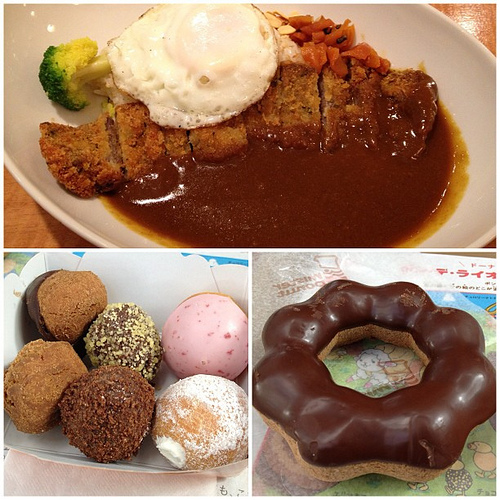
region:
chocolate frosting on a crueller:
[276, 376, 318, 412]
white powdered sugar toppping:
[207, 386, 227, 416]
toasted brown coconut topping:
[85, 395, 135, 420]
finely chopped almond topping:
[121, 325, 141, 345]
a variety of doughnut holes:
[0, 260, 239, 469]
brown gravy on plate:
[259, 177, 326, 222]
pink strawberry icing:
[187, 319, 228, 354]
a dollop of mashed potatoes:
[149, 40, 232, 97]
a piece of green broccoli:
[40, 48, 97, 102]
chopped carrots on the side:
[314, 19, 363, 66]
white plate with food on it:
[0, 29, 493, 242]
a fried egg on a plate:
[108, 8, 284, 106]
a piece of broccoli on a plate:
[30, 31, 152, 116]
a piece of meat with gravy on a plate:
[46, 62, 470, 229]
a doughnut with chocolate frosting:
[296, 264, 494, 447]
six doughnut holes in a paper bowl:
[3, 266, 237, 470]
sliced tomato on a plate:
[256, 27, 395, 79]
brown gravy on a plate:
[99, 96, 455, 256]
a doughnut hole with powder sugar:
[139, 369, 241, 499]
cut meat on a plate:
[47, 74, 437, 197]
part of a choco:
[333, 400, 361, 434]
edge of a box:
[144, 453, 184, 482]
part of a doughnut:
[302, 375, 350, 461]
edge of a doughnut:
[295, 427, 360, 479]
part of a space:
[368, 344, 403, 386]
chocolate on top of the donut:
[291, 287, 485, 478]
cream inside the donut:
[153, 391, 202, 482]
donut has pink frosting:
[173, 289, 251, 369]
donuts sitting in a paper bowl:
[25, 265, 260, 315]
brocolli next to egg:
[45, 36, 145, 111]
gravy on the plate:
[195, 132, 460, 222]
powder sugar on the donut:
[162, 374, 245, 450]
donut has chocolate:
[23, 258, 49, 343]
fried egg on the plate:
[117, 21, 318, 126]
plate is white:
[422, 24, 495, 105]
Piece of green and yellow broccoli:
[32, 33, 109, 113]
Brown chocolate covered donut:
[262, 273, 487, 482]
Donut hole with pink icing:
[149, 287, 254, 382]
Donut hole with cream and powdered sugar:
[150, 373, 246, 475]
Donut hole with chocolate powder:
[52, 359, 160, 468]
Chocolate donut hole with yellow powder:
[73, 293, 168, 388]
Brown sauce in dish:
[122, 130, 463, 257]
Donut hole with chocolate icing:
[12, 259, 111, 344]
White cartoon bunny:
[345, 332, 403, 402]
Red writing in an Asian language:
[415, 263, 498, 280]